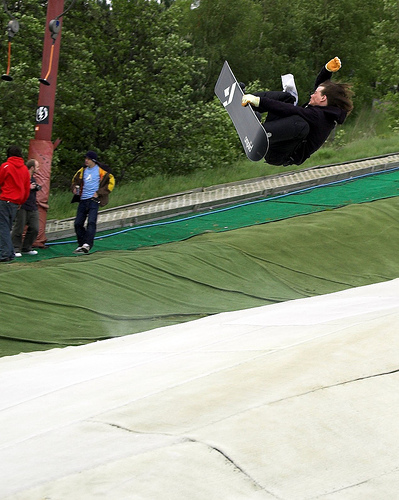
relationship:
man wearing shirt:
[66, 146, 115, 257] [78, 168, 102, 203]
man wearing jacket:
[66, 146, 115, 257] [66, 164, 119, 208]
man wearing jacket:
[3, 147, 34, 267] [2, 156, 33, 207]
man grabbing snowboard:
[244, 46, 354, 173] [209, 62, 274, 167]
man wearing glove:
[244, 46, 354, 173] [240, 91, 260, 111]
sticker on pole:
[31, 103, 52, 126] [26, 6, 69, 248]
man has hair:
[244, 46, 354, 173] [321, 79, 351, 113]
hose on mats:
[33, 175, 398, 245] [16, 163, 398, 246]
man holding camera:
[25, 156, 45, 265] [36, 181, 47, 195]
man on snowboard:
[244, 46, 354, 173] [209, 62, 274, 167]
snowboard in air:
[209, 62, 274, 167] [2, 4, 398, 348]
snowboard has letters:
[209, 62, 274, 167] [243, 137, 258, 158]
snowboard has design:
[209, 62, 274, 167] [217, 81, 242, 111]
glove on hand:
[321, 55, 344, 76] [323, 53, 346, 78]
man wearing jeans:
[66, 146, 115, 257] [71, 198, 101, 253]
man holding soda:
[25, 156, 45, 265] [34, 180, 45, 198]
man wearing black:
[244, 46, 354, 173] [252, 72, 337, 169]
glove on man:
[321, 55, 344, 76] [244, 46, 354, 173]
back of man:
[1, 159, 29, 257] [3, 147, 34, 267]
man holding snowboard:
[244, 46, 354, 173] [209, 62, 274, 167]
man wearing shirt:
[244, 46, 354, 173] [262, 92, 342, 160]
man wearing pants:
[244, 46, 354, 173] [259, 113, 308, 167]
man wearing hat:
[66, 146, 115, 257] [84, 151, 96, 163]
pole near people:
[26, 6, 69, 248] [5, 146, 132, 266]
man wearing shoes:
[25, 156, 45, 265] [15, 249, 42, 259]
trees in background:
[3, 3, 398, 185] [3, 6, 398, 330]